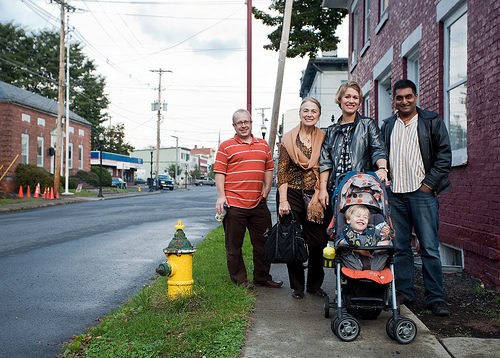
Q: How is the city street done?
A: The city street is paved.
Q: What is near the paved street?
A: A strip of green grass is near the paved street.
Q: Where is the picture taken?
A: The sidewalk.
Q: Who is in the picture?
A: Family.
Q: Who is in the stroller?
A: A baby boy.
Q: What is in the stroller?
A: A baby.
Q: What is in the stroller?
A: A baby.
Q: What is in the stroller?
A: A toddler.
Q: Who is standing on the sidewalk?
A: Four people.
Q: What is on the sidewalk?
A: A baby stroller.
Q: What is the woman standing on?
A: A sidewalk.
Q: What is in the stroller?
A: A child.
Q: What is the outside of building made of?
A: Red brick.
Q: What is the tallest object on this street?
A: Power lines.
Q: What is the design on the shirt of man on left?
A: Striped.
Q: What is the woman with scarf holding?
A: Black bag.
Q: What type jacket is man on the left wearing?
A: Black leather.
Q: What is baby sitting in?
A: Stroller.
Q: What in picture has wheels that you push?
A: Stroller.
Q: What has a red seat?
A: Stroller.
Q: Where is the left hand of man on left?
A: Pocket.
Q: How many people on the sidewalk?
A: Five.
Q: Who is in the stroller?
A: A child.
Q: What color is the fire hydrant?
A: Yellow and green.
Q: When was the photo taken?
A: Daytime.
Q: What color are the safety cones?
A: Orange.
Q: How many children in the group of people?
A: One.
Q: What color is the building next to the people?
A: Red.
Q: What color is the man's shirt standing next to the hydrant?
A: Red and white.